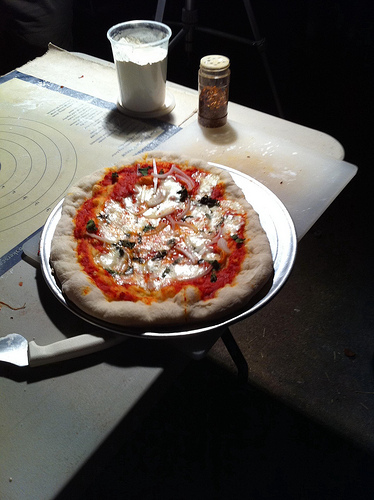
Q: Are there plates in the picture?
A: Yes, there is a plate.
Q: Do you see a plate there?
A: Yes, there is a plate.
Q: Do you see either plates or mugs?
A: Yes, there is a plate.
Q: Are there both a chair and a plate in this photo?
A: No, there is a plate but no chairs.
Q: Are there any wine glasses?
A: No, there are no wine glasses.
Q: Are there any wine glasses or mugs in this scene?
A: No, there are no wine glasses or mugs.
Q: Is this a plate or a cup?
A: This is a plate.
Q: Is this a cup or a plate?
A: This is a plate.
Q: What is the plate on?
A: The plate is on the table.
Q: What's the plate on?
A: The plate is on the table.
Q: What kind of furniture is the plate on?
A: The plate is on the table.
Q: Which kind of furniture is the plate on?
A: The plate is on the table.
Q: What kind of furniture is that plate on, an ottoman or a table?
A: The plate is on a table.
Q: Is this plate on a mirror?
A: No, the plate is on the table.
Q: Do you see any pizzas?
A: Yes, there is a pizza.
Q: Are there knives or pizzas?
A: Yes, there is a pizza.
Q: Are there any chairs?
A: No, there are no chairs.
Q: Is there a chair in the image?
A: No, there are no chairs.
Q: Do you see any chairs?
A: No, there are no chairs.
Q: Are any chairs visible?
A: No, there are no chairs.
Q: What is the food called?
A: The food is a pizza.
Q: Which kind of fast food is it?
A: The food is a pizza.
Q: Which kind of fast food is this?
A: That is a pizza.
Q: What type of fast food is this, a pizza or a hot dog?
A: That is a pizza.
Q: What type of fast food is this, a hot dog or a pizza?
A: That is a pizza.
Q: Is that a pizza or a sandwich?
A: That is a pizza.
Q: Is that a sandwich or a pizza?
A: That is a pizza.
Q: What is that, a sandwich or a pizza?
A: That is a pizza.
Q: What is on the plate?
A: The pizza is on the plate.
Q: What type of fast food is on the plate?
A: The food is a pizza.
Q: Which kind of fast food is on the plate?
A: The food is a pizza.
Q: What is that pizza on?
A: The pizza is on the plate.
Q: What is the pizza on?
A: The pizza is on the plate.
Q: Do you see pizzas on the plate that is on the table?
A: Yes, there is a pizza on the plate.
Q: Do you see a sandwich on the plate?
A: No, there is a pizza on the plate.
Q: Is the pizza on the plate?
A: Yes, the pizza is on the plate.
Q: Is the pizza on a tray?
A: No, the pizza is on the plate.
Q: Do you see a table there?
A: Yes, there is a table.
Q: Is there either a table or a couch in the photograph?
A: Yes, there is a table.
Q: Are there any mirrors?
A: No, there are no mirrors.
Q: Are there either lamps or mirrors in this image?
A: No, there are no mirrors or lamps.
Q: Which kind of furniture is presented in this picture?
A: The furniture is a table.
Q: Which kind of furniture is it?
A: The piece of furniture is a table.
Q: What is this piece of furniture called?
A: This is a table.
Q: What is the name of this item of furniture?
A: This is a table.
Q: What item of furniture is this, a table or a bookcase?
A: This is a table.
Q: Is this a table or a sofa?
A: This is a table.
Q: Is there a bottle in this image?
A: Yes, there is a bottle.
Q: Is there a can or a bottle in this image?
A: Yes, there is a bottle.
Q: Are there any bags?
A: No, there are no bags.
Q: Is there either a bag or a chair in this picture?
A: No, there are no bags or chairs.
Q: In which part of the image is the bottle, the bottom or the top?
A: The bottle is in the top of the image.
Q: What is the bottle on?
A: The bottle is on the table.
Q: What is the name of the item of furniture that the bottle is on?
A: The piece of furniture is a table.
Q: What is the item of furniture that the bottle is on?
A: The piece of furniture is a table.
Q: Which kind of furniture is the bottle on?
A: The bottle is on the table.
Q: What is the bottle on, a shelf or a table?
A: The bottle is on a table.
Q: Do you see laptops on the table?
A: No, there is a bottle on the table.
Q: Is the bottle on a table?
A: Yes, the bottle is on a table.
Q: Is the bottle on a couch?
A: No, the bottle is on a table.